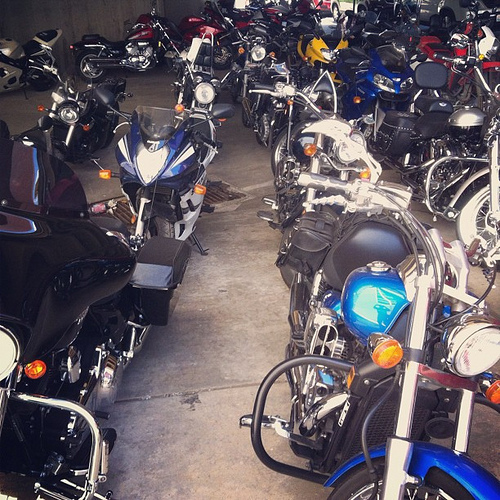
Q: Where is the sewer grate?
A: In the middle of the floor.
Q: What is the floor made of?
A: Concrete.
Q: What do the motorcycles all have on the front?
A: Head lights.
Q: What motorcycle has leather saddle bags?
A: The black and silver one on the right.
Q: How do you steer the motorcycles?
A: With the handlebars.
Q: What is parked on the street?
A: Motorcycles.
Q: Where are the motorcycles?
A: The motorcycles are next to each other.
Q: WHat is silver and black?
A: The handle on the motorcycle.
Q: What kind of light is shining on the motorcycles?
A: Sunlight.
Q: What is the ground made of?
A: Cement.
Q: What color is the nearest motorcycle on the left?
A: Black.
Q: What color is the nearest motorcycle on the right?
A: Blue.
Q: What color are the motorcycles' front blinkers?
A: Orange.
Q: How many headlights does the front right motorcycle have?
A: One.